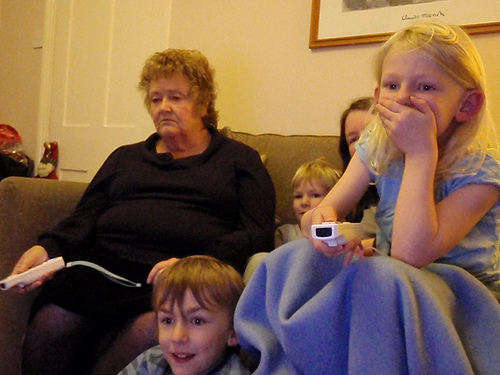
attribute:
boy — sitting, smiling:
[113, 252, 253, 374]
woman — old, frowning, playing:
[2, 49, 277, 374]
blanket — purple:
[234, 236, 499, 374]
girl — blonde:
[234, 20, 500, 374]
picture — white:
[319, 1, 500, 43]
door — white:
[36, 2, 174, 177]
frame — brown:
[309, 2, 500, 49]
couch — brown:
[0, 121, 344, 374]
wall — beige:
[174, 5, 499, 143]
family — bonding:
[1, 25, 498, 374]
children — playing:
[108, 20, 500, 373]